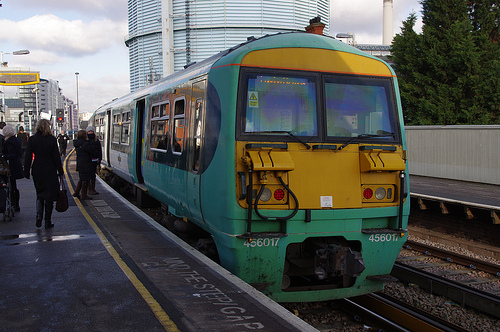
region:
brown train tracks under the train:
[286, 214, 498, 330]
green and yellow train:
[86, 30, 412, 305]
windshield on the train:
[241, 70, 397, 141]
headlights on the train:
[255, 184, 390, 202]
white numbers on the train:
[238, 231, 400, 248]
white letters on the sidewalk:
[158, 252, 267, 330]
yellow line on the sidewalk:
[73, 200, 176, 330]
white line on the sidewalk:
[140, 208, 310, 330]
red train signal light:
[53, 103, 65, 126]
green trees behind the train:
[386, 1, 499, 125]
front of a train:
[236, 30, 426, 257]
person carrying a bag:
[33, 101, 72, 237]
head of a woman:
[30, 112, 57, 135]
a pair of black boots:
[31, 185, 66, 234]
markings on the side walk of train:
[83, 163, 268, 325]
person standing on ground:
[63, 123, 113, 204]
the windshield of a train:
[247, 67, 397, 139]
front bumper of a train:
[242, 198, 416, 297]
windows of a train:
[141, 98, 214, 154]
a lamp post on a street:
[52, 52, 91, 142]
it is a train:
[96, 22, 403, 303]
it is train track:
[434, 244, 474, 299]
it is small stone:
[414, 294, 449, 310]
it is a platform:
[12, 232, 180, 329]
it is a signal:
[54, 107, 67, 124]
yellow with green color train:
[209, 30, 419, 295]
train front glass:
[239, 66, 396, 141]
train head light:
[372, 183, 400, 201]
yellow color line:
[84, 241, 149, 328]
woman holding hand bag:
[54, 174, 71, 215]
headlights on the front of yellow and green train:
[236, 148, 297, 223]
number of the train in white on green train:
[361, 223, 405, 247]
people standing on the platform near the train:
[7, 63, 134, 266]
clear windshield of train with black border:
[236, 58, 400, 158]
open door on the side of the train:
[125, 93, 153, 193]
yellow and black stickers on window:
[242, 88, 263, 112]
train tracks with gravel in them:
[412, 234, 488, 319]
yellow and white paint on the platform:
[93, 223, 228, 329]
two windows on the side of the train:
[144, 93, 187, 163]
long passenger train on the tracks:
[81, 27, 432, 327]